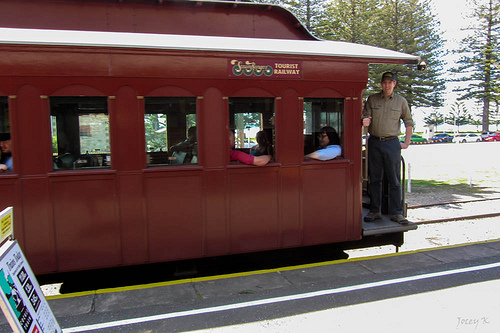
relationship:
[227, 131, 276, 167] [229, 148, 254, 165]
man on pink shirt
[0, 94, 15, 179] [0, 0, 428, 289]
window on train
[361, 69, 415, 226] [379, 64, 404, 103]
man wearing hat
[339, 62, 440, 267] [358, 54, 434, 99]
man wearing hat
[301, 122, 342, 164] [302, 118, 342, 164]
lady wearing glasses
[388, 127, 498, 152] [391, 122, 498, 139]
parking area for vehicles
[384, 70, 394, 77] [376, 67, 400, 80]
lettering on hat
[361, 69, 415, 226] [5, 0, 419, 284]
man standing on red train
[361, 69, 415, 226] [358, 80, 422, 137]
man wearing a shirt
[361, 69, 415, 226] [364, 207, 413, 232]
man wearing grey shoes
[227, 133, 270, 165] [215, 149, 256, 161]
man has shirt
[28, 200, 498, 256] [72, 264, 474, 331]
line on train platform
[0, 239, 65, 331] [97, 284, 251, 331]
sign on sidewalk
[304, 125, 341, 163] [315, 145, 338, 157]
lady in shirt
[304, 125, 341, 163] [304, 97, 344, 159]
lady sitting in window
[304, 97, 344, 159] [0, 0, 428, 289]
window of train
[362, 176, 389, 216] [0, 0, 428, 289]
stairs on side of train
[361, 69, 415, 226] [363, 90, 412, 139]
man wearing shirt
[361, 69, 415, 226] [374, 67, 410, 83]
man wearing hat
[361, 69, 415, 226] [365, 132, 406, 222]
man wearing blue pants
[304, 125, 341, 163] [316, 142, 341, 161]
lady wearing shirt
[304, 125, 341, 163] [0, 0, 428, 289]
lady inside train